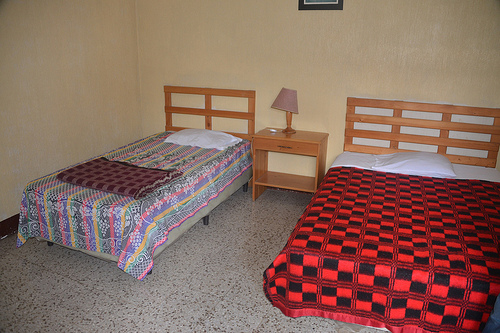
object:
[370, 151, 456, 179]
comforter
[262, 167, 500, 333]
blanket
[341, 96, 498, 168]
headboard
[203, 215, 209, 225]
feet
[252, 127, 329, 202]
stand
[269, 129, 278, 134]
table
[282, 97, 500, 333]
bed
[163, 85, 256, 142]
headboard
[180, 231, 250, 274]
ground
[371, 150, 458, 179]
pillow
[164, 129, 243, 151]
pillow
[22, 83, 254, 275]
bed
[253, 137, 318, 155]
drawer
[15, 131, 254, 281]
sheet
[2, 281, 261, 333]
floor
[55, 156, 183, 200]
bedspread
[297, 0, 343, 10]
picture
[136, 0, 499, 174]
wall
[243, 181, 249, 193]
leg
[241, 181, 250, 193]
leg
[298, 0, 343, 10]
frame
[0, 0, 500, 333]
room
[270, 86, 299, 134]
lamp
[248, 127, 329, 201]
end table